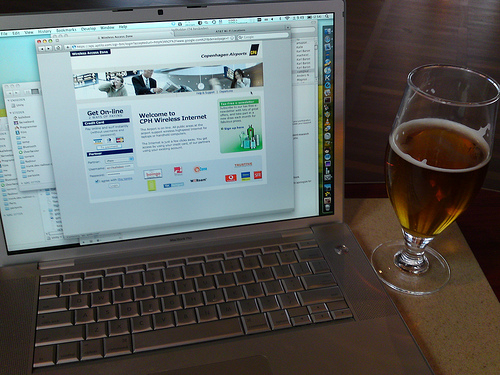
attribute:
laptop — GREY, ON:
[0, 0, 435, 370]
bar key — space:
[131, 317, 241, 352]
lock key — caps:
[35, 309, 69, 329]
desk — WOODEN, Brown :
[4, 203, 499, 371]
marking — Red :
[388, 158, 392, 167]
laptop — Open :
[3, 13, 462, 373]